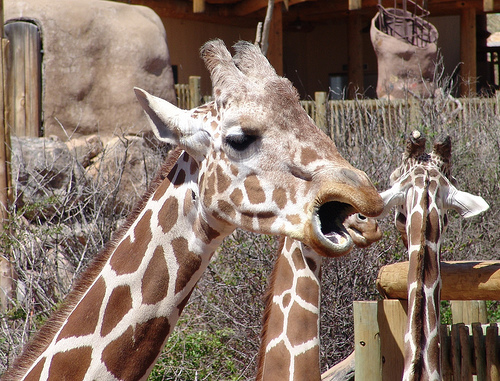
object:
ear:
[131, 85, 209, 153]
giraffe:
[0, 36, 386, 381]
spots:
[242, 169, 266, 205]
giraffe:
[375, 128, 491, 379]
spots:
[271, 182, 289, 210]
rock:
[2, 2, 177, 140]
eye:
[222, 126, 261, 154]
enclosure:
[10, 88, 500, 380]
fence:
[171, 75, 499, 163]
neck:
[0, 105, 221, 379]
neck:
[401, 183, 451, 381]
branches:
[395, 44, 467, 161]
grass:
[141, 324, 257, 379]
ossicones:
[196, 36, 266, 101]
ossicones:
[400, 128, 430, 160]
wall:
[177, 0, 202, 66]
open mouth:
[307, 187, 387, 258]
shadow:
[436, 255, 500, 301]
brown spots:
[43, 343, 95, 381]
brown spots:
[259, 339, 293, 381]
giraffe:
[255, 234, 327, 381]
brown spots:
[292, 344, 323, 381]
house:
[106, 0, 499, 100]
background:
[2, 3, 500, 139]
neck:
[258, 235, 325, 380]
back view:
[373, 126, 486, 381]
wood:
[188, 75, 201, 110]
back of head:
[375, 127, 489, 250]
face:
[197, 36, 386, 258]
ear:
[444, 184, 490, 220]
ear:
[375, 183, 405, 220]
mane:
[3, 143, 183, 380]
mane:
[409, 170, 433, 381]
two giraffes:
[251, 127, 491, 381]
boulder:
[369, 6, 446, 101]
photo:
[0, 0, 499, 381]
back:
[402, 140, 449, 233]